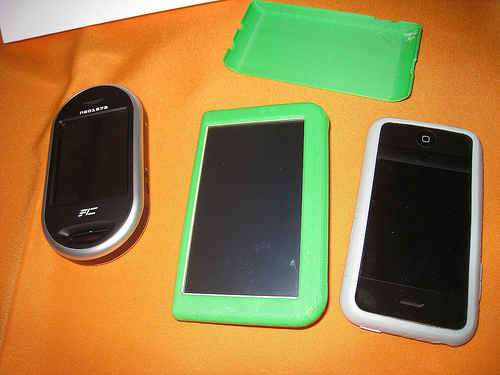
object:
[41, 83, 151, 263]
phone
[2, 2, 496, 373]
cloth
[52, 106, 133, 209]
screen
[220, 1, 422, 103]
cover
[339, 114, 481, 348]
phone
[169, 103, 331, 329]
phone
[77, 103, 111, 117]
letters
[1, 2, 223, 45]
paper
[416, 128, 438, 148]
button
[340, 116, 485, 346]
case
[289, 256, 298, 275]
fingerprint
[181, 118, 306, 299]
screen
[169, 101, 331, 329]
case